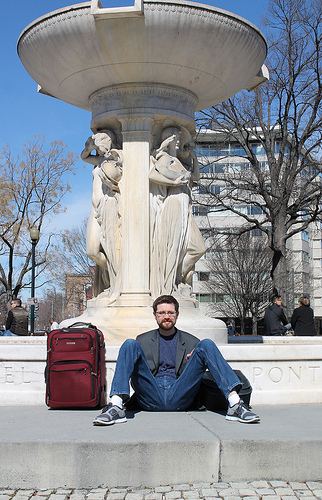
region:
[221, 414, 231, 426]
part of a floor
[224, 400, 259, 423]
Athletic shoe on a guy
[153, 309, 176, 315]
Glasses worn by a man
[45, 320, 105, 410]
A red luggage bag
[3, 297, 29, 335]
A man wearing a vest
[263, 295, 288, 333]
Man wearing a suit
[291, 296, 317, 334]
Woman wearing a black coat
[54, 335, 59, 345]
Zipper on a luggage bag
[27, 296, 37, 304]
Sign up on a pole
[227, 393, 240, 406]
White sock on left foot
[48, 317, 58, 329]
Man wearing a white shirt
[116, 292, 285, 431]
this is a man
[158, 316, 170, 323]
the man is light skinned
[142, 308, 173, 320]
this is a spectacle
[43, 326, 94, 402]
this is a bag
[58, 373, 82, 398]
the bag is red in color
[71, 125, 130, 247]
this is a monument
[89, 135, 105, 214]
the monument is white in color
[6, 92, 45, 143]
this is the sky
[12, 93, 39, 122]
the sky is blue in color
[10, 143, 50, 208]
this is a tree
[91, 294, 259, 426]
a man sitting in front of a statue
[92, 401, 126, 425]
the man's left shoe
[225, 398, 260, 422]
the man's right shoe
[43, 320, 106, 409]
the suitcase is red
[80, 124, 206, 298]
a sculpture of two women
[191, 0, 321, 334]
the tree has no leaves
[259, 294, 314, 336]
two people wearing black facing away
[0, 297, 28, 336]
a man in a leather jacket facing away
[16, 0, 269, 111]
the bowl on the top of the statue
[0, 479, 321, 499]
the cobblestones in front of the man